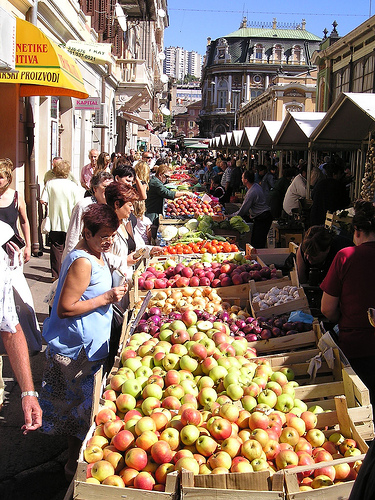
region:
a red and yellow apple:
[210, 417, 231, 439]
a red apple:
[173, 264, 184, 271]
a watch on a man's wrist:
[18, 386, 44, 399]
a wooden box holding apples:
[71, 417, 181, 498]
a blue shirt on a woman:
[35, 248, 125, 362]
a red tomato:
[167, 246, 179, 254]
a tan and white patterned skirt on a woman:
[29, 344, 107, 444]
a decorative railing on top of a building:
[240, 15, 308, 30]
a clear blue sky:
[162, 0, 372, 55]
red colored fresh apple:
[153, 277, 166, 288]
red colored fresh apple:
[166, 278, 175, 287]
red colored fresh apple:
[175, 276, 188, 286]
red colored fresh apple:
[209, 276, 220, 288]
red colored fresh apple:
[220, 275, 229, 288]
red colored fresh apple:
[232, 272, 241, 283]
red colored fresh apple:
[180, 264, 191, 275]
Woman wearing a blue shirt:
[36, 199, 129, 472]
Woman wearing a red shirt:
[316, 199, 374, 361]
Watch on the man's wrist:
[14, 377, 41, 402]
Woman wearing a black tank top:
[0, 155, 32, 268]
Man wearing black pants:
[230, 165, 273, 248]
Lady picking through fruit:
[143, 164, 198, 214]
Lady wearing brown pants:
[32, 160, 86, 282]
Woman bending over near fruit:
[293, 221, 354, 296]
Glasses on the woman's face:
[94, 230, 118, 245]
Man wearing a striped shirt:
[215, 158, 236, 199]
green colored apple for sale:
[180, 423, 195, 443]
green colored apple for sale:
[160, 427, 179, 447]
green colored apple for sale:
[208, 450, 231, 470]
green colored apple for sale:
[121, 381, 141, 397]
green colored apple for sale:
[134, 365, 152, 378]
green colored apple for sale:
[122, 357, 141, 369]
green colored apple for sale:
[162, 350, 179, 369]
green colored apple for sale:
[179, 356, 197, 372]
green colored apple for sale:
[208, 363, 224, 383]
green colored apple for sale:
[275, 392, 294, 412]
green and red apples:
[96, 403, 346, 489]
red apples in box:
[142, 312, 302, 338]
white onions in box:
[253, 284, 297, 306]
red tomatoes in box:
[159, 239, 243, 256]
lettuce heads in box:
[197, 215, 248, 235]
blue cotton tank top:
[38, 248, 113, 357]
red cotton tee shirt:
[319, 242, 374, 345]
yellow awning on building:
[1, 19, 90, 98]